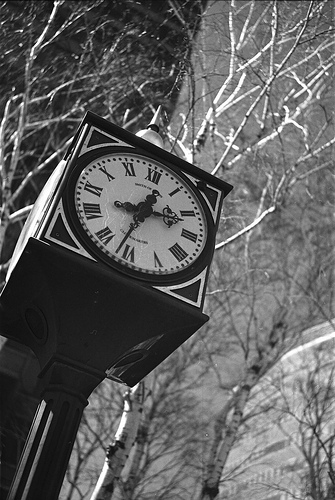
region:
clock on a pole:
[0, 104, 232, 497]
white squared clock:
[0, 117, 241, 362]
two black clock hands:
[116, 187, 180, 253]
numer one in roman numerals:
[169, 180, 183, 198]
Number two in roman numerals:
[179, 208, 193, 219]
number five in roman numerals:
[151, 250, 166, 270]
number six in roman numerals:
[121, 240, 138, 266]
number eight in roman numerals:
[80, 199, 106, 225]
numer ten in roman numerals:
[95, 165, 117, 182]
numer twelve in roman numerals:
[138, 162, 165, 185]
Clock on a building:
[62, 119, 230, 281]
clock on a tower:
[63, 134, 226, 301]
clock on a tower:
[75, 111, 222, 310]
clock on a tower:
[70, 125, 221, 292]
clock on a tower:
[67, 143, 282, 310]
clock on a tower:
[67, 124, 205, 264]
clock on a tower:
[60, 125, 221, 299]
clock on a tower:
[69, 136, 218, 287]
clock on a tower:
[65, 129, 210, 291]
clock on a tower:
[59, 116, 205, 272]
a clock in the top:
[61, 136, 231, 276]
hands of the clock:
[110, 205, 147, 239]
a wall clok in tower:
[46, 118, 289, 410]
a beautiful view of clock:
[40, 93, 278, 449]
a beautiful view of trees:
[218, 294, 333, 446]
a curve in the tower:
[18, 419, 53, 483]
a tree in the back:
[76, 396, 166, 496]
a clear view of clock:
[53, 140, 252, 320]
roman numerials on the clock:
[169, 226, 199, 259]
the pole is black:
[32, 405, 60, 498]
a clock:
[82, 159, 215, 271]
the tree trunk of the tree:
[116, 411, 139, 450]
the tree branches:
[258, 191, 291, 213]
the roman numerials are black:
[163, 244, 190, 260]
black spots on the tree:
[102, 437, 127, 462]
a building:
[251, 437, 293, 490]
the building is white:
[232, 435, 299, 489]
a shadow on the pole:
[60, 423, 76, 458]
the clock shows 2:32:
[70, 134, 199, 289]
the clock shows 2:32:
[62, 132, 209, 298]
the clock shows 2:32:
[69, 147, 235, 323]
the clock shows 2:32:
[73, 148, 215, 285]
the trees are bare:
[220, 195, 309, 355]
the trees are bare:
[210, 222, 307, 391]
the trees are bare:
[228, 224, 322, 409]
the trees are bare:
[192, 269, 320, 409]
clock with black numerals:
[53, 138, 221, 294]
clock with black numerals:
[60, 139, 232, 296]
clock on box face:
[49, 137, 218, 292]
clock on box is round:
[60, 140, 220, 296]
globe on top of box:
[128, 95, 171, 154]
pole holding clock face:
[1, 354, 115, 499]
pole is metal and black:
[1, 356, 104, 499]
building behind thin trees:
[208, 306, 334, 499]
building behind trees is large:
[210, 314, 334, 498]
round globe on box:
[130, 124, 165, 151]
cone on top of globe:
[147, 101, 161, 130]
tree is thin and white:
[74, 381, 159, 499]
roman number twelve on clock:
[143, 162, 163, 189]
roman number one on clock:
[162, 183, 186, 202]